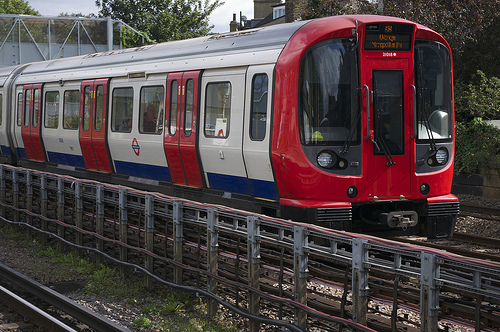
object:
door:
[78, 76, 114, 175]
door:
[20, 83, 48, 163]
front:
[276, 15, 460, 242]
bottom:
[0, 157, 460, 242]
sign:
[362, 22, 414, 53]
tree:
[453, 66, 499, 116]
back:
[71, 1, 499, 36]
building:
[253, 0, 341, 25]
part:
[462, 205, 480, 218]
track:
[385, 207, 499, 261]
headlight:
[313, 150, 341, 170]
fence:
[1, 163, 499, 331]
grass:
[64, 257, 102, 276]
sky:
[29, 0, 102, 16]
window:
[111, 88, 132, 133]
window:
[203, 80, 231, 140]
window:
[43, 91, 61, 128]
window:
[252, 73, 268, 140]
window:
[302, 36, 357, 145]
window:
[413, 36, 454, 140]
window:
[138, 84, 163, 134]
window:
[64, 89, 80, 131]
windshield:
[373, 68, 405, 154]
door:
[364, 57, 411, 197]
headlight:
[434, 146, 450, 166]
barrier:
[0, 16, 119, 59]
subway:
[0, 15, 457, 248]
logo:
[131, 138, 141, 156]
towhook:
[383, 211, 417, 230]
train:
[6, 12, 464, 233]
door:
[160, 70, 210, 192]